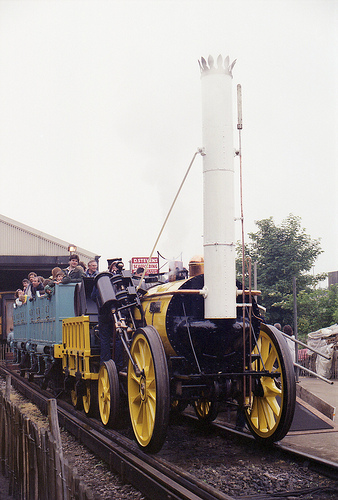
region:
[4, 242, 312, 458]
steam engine pulling passengers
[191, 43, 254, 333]
white steam stack on a steam engine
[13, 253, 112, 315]
crowd of people in a steam engine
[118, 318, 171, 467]
large wheel on a steam engine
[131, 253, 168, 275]
red and white signage shaped like an arrow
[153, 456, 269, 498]
railroad tracks filled with gravel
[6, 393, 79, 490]
wooden picket fence beside a steam engine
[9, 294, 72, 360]
blue passenger bucket connected to a steam engine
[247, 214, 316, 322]
green tree with lots of leaves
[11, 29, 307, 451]
people riding on a steam engine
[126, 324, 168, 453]
front right steam engine wheel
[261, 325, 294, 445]
front right steam engine wheel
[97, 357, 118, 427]
rear right steam engine wheel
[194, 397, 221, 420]
rear left steam engine wheel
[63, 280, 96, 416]
steam engine coal carrier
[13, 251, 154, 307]
9 visible faces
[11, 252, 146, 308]
12 people are seen riding in train car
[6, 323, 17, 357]
engineer with back to train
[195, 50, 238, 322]
steam engine smoke stack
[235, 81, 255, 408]
steam engine locomotive whistle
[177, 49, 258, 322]
Steam pipe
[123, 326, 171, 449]
Wheel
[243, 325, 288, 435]
Black wheel with luxurious yellow interior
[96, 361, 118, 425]
Black wheel with luxurious yellow interior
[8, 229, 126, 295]
Group of people enjoying the ride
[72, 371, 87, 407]
Black wheel with luxurious yellow interior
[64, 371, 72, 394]
Black wheel with luxurious yellow interior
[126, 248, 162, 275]
Advertisement for something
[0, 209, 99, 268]
Railway station roof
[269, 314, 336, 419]
Ramp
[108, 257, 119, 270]
the head of a person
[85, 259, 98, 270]
the head of a person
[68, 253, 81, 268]
the head of a person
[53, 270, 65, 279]
the head of a person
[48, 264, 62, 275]
the head of a person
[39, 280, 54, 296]
the head of a person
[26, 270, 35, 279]
the head of a person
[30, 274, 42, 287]
the head of a person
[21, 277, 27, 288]
the head of a person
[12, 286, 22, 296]
the head of a person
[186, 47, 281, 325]
steam stack on a steam engine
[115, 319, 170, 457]
train wheel on a steam engine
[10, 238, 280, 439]
people riding a steam engine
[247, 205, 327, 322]
tall green tree next to a steam engine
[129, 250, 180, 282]
red and white arrow sign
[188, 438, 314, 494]
railroad filled with gravel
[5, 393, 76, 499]
wooden slat fence next to a train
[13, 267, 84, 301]
people riding in an open air train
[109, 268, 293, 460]
yellow and black steam engine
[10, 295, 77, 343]
blue passenger car